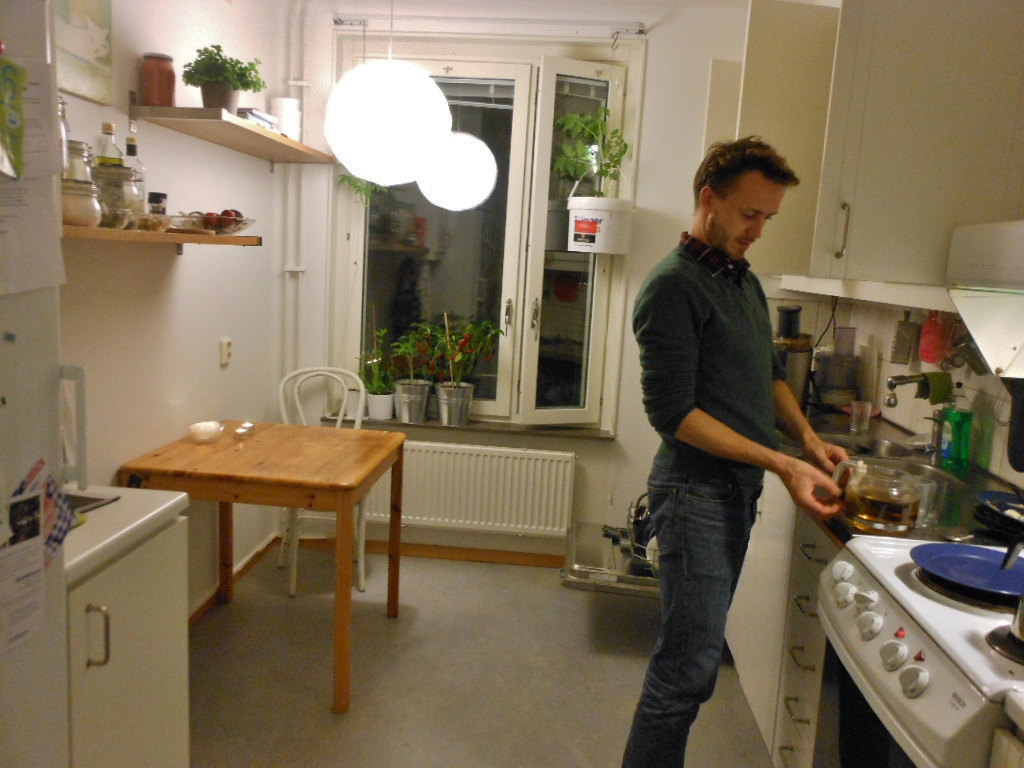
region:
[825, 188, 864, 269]
gold handle on cabinet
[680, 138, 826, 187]
the man's brown hair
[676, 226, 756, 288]
collar on the man's shirt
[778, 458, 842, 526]
right hand of the man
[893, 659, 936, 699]
knob on the stove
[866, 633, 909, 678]
small white knob on the stove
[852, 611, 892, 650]
white twisting knob on stove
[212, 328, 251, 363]
outlet on the wall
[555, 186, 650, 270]
bucket hanging from ceiling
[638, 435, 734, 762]
man is wearing jeans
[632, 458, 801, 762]
jeans are blue in color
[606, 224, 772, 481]
shirt is grey in color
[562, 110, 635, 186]
plant inside of bucket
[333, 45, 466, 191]
light hanging from ceilding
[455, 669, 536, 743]
the floor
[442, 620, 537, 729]
the floor is grey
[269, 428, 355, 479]
the table is brown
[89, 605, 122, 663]
the handle on the cabinet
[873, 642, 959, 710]
knobs on the stove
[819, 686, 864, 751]
the oven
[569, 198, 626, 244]
a white bucket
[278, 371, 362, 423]
a chair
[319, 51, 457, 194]
large light globe hanging from ceiling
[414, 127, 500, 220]
light globe reflecting from window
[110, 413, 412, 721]
wooden dining table against wall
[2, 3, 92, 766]
refrigerator covered with paper articles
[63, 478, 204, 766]
small white freezer-like chest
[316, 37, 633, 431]
large window in kitchen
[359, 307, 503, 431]
potted plants sitting in window sill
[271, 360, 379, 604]
chair behind wooden dining table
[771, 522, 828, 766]
whole bunch of drawers in kitchen cabinet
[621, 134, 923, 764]
man standing in front of a coffee pot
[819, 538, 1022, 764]
a blue plate on top of a stove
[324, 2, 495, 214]
two round paper lights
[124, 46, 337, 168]
a pot and a green plant sitting on a shelf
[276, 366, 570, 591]
a white radiator behind a white chair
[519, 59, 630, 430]
an opened white window with a silver handle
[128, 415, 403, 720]
two votive candles on top of a table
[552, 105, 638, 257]
a green plant in a white planter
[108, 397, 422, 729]
small table against wall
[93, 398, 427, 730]
small table is wooden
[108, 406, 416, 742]
small table is brown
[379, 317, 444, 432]
plant in front of window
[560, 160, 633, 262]
white container is hanging in window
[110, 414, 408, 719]
wooden dining table against wall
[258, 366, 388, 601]
white dining chair behind table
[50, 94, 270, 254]
shelf full of cooking items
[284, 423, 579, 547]
white radiator vent under window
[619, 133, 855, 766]
man busy in kitchen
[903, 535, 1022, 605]
blue serving plate on top of burner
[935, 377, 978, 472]
bottle of green dishwashing liquid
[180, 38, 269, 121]
potted green plant on shelf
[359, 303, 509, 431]
potted plants on window sill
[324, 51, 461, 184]
A round white light in a kitchen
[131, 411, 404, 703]
A wooden table in a kitchen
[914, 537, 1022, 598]
A blue plate on a stove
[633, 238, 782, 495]
A green shirt on a man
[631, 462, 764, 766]
Blue jeans on a man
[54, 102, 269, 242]
A shelf with items on it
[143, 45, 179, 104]
A jar on a shelf